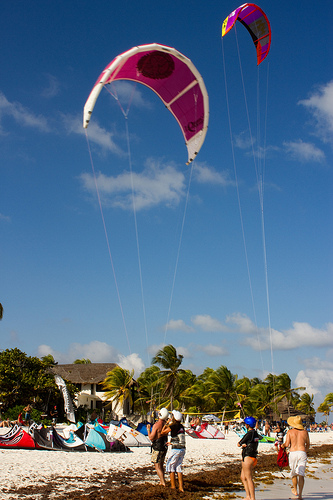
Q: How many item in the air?
A: Two.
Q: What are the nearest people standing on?
A: Seaweed.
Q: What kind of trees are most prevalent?
A: Palm.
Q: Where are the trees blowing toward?
A: The left.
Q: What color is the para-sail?
A: Purple.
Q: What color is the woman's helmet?
A: Blue.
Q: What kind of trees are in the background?
A: Palm trees.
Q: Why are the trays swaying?
A: Wind.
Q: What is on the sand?
A: Tents.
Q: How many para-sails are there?
A: 2.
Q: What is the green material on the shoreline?
A: Seaweed.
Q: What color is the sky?
A: Bright blue.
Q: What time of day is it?
A: Day time.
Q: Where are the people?
A: The beach.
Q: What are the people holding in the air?
A: Kites.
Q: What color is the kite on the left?
A: Pink and white.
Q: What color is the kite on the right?
A: Purple, red and yellow.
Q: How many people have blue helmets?
A: One.